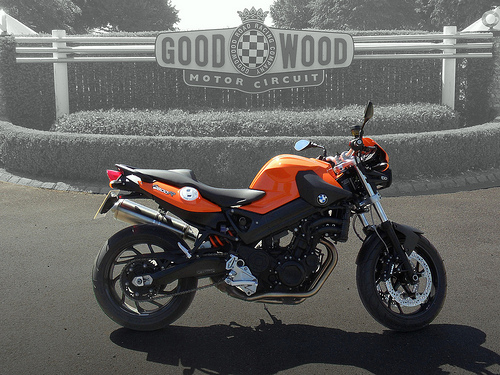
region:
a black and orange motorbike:
[101, 62, 420, 367]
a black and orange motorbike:
[183, 157, 408, 346]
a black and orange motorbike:
[98, 47, 323, 369]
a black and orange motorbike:
[141, 92, 353, 357]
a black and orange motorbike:
[187, 142, 397, 357]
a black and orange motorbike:
[160, 146, 405, 371]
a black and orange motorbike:
[189, 142, 346, 365]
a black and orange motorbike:
[143, 98, 339, 355]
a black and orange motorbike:
[138, 141, 332, 357]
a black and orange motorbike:
[140, 101, 336, 346]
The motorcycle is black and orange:
[78, 98, 450, 345]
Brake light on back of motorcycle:
[96, 162, 128, 189]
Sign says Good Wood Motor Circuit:
[143, 18, 365, 98]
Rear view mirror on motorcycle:
[287, 130, 322, 157]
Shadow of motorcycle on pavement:
[91, 318, 499, 373]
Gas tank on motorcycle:
[173, 179, 203, 211]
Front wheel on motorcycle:
[346, 214, 456, 344]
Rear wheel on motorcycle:
[79, 216, 204, 338]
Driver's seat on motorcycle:
[202, 156, 258, 228]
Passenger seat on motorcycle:
[130, 149, 185, 197]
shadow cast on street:
[108, 323, 498, 371]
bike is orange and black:
[111, 155, 394, 240]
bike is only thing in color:
[1, 1, 498, 371]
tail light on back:
[104, 167, 124, 180]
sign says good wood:
[151, 8, 355, 90]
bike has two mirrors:
[294, 101, 376, 156]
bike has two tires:
[90, 220, 447, 332]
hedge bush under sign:
[49, 106, 469, 137]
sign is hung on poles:
[14, 28, 496, 121]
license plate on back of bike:
[95, 190, 122, 215]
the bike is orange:
[65, 91, 483, 250]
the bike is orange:
[99, 71, 447, 366]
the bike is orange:
[126, 97, 336, 360]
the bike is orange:
[89, 33, 369, 360]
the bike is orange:
[77, 33, 321, 276]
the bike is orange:
[126, 44, 361, 339]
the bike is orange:
[121, 121, 396, 371]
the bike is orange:
[120, 131, 391, 373]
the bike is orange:
[152, 131, 379, 370]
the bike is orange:
[159, 61, 372, 352]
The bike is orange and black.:
[72, 110, 449, 335]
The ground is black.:
[13, 271, 82, 357]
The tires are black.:
[72, 211, 457, 342]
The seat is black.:
[111, 151, 268, 213]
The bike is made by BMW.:
[309, 189, 334, 209]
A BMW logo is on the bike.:
[305, 181, 337, 210]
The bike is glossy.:
[91, 131, 448, 338]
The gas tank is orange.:
[223, 125, 337, 216]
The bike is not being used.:
[66, 137, 475, 350]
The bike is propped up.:
[211, 236, 308, 336]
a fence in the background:
[3, 14, 497, 144]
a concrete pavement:
[6, 188, 493, 368]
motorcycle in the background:
[56, 132, 482, 337]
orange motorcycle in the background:
[56, 85, 493, 374]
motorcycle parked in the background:
[48, 58, 470, 350]